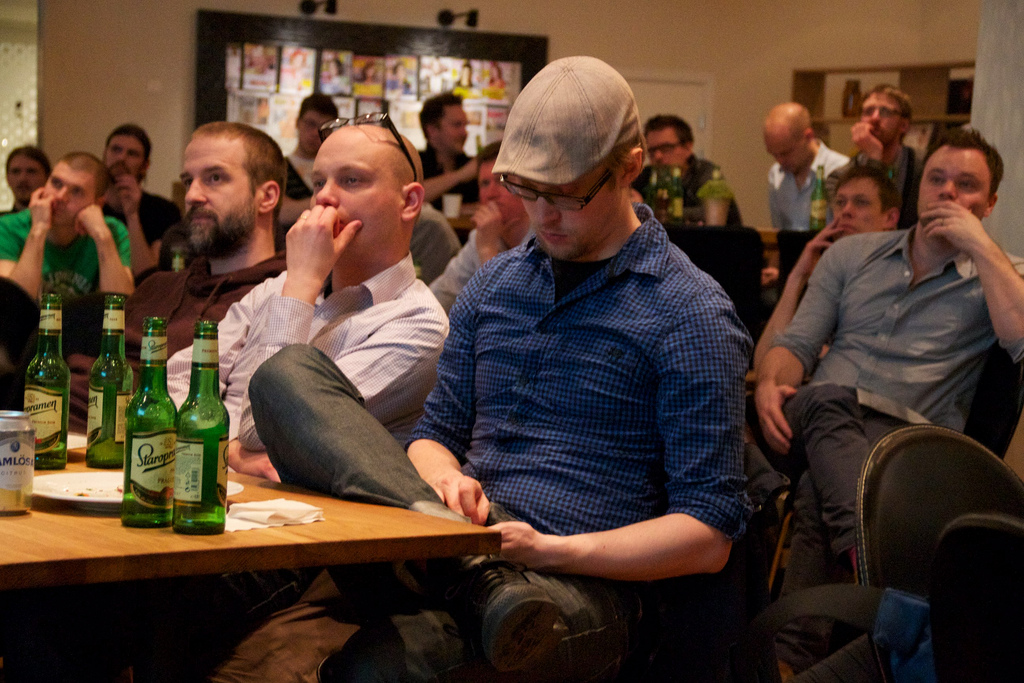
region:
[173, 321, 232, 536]
beer bottle is on the table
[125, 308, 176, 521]
beer bottle is on the table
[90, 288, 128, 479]
beer bottle is on the table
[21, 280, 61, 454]
beer bottle is on the table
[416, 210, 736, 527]
black and blue shirt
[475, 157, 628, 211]
man has eyeglasses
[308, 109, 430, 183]
man has eyeglasses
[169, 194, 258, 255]
man has a beard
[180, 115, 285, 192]
man has short hair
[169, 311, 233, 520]
Green beer bottle on the table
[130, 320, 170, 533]
Green beer bottle on the table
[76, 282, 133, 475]
Green beer bottle on the table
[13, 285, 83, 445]
Green beer bottle on the table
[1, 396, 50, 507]
beer can on the table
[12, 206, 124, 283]
man wearing a green shirt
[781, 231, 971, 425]
man wearing a grey shirt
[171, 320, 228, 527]
empty green glass beer bottle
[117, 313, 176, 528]
empty green glass beer bottle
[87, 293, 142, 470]
empty green glass beer bottle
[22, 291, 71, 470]
empty green glass beer bottle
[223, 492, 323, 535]
white folded napkin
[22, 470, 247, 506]
dirty white glass plate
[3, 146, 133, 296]
person in a green shirt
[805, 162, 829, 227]
empty green glass beer bottle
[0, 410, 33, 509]
beer can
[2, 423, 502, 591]
wood table top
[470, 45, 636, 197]
Man wearing a brown hat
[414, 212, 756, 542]
Man wearing a black and blue shirt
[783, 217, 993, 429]
Man wearing a gray shirt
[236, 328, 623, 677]
Man wearing black pants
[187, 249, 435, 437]
Man wearing a white shirt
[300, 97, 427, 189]
Man with glasses on his head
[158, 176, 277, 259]
Man with a full beard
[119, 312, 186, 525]
bottle of beer on the table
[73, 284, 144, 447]
bottle of beer on the table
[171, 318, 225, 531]
an empty beer bottle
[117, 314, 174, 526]
an empty beer bottle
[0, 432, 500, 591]
a wooden table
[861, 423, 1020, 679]
the back of a chair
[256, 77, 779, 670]
A person is sitting down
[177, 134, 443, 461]
A person is sitting down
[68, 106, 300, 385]
A person is sitting down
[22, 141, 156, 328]
A person is sitting down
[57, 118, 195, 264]
A person is sitting down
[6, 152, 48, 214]
A person is sitting down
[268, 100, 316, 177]
A person is sitting down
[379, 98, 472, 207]
A person is sitting down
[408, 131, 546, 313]
A person is sitting down